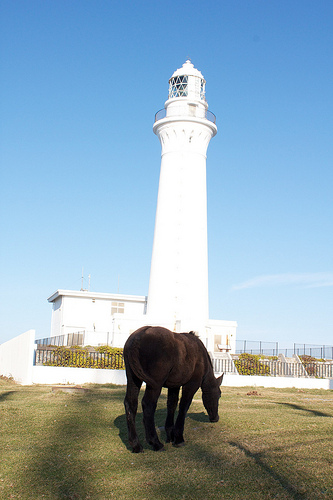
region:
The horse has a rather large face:
[204, 374, 239, 451]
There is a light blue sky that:
[275, 300, 288, 327]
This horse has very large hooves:
[176, 434, 199, 458]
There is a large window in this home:
[112, 296, 124, 336]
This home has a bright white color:
[69, 303, 73, 313]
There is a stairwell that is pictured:
[281, 358, 313, 403]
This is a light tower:
[144, 59, 233, 339]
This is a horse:
[106, 317, 239, 444]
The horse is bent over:
[133, 318, 234, 453]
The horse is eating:
[205, 403, 226, 430]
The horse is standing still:
[110, 323, 231, 456]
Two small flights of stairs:
[210, 346, 307, 375]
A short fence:
[38, 346, 120, 366]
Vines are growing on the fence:
[48, 346, 120, 369]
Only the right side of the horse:
[137, 333, 216, 435]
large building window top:
[154, 51, 216, 115]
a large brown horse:
[102, 326, 223, 441]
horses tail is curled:
[120, 313, 161, 400]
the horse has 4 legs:
[111, 365, 204, 475]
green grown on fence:
[45, 332, 119, 386]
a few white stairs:
[217, 341, 314, 387]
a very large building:
[161, 62, 220, 148]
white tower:
[154, 50, 214, 332]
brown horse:
[120, 325, 228, 445]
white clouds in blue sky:
[22, 35, 69, 81]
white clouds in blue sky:
[229, 269, 270, 289]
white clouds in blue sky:
[245, 293, 276, 312]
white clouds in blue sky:
[238, 176, 303, 220]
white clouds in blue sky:
[263, 122, 302, 164]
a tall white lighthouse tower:
[119, 53, 220, 288]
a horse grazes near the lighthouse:
[114, 319, 228, 457]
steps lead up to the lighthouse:
[276, 348, 316, 382]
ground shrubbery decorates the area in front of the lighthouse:
[231, 349, 290, 379]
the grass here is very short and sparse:
[2, 387, 331, 497]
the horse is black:
[119, 320, 233, 455]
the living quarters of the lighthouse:
[41, 282, 241, 354]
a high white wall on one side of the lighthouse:
[0, 329, 41, 385]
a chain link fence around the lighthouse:
[34, 327, 331, 360]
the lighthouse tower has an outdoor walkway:
[145, 58, 223, 140]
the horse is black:
[127, 322, 224, 450]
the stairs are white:
[212, 353, 232, 375]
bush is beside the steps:
[212, 350, 266, 384]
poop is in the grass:
[244, 388, 268, 409]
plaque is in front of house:
[214, 338, 231, 356]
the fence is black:
[238, 335, 323, 363]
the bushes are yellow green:
[48, 343, 131, 369]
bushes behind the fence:
[39, 345, 319, 376]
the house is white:
[54, 287, 240, 354]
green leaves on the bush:
[248, 355, 257, 366]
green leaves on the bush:
[59, 343, 73, 356]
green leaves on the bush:
[80, 356, 89, 364]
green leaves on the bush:
[97, 354, 111, 369]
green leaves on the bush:
[111, 346, 118, 360]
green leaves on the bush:
[115, 361, 124, 373]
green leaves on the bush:
[100, 338, 110, 359]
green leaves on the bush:
[79, 351, 103, 370]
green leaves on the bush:
[244, 352, 261, 378]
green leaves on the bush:
[298, 355, 306, 365]